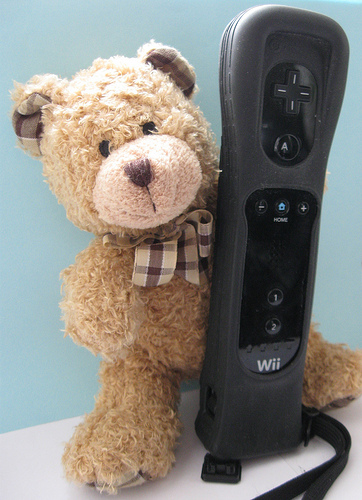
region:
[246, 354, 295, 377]
the wii is gray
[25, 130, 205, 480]
the bear is brown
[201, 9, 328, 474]
the controller is black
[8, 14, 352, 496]
the bear is holding the controller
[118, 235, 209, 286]
the scarf is plaid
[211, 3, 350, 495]
the remote has a strap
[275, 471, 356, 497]
the strap is black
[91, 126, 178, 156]
the bear has eyes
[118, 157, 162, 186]
the bear has a nose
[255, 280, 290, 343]
the remote has buttons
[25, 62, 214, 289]
The bear is brown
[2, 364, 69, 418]
The background is blue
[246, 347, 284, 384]
The controller is for a Wii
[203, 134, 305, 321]
The controller is black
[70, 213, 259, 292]
The bear has a tie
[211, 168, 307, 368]
The controller has buttons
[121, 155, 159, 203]
The bear's nose is dark brown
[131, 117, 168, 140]
The bear's eyes are black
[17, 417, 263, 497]
The bear is on a white object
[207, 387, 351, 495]
The Wii controller has a strap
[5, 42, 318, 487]
the bear is brown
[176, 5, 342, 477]
game controller in front of bear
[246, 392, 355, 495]
controller has a strap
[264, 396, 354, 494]
the strap is black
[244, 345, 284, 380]
controller has white lettering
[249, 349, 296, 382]
the lettering says wii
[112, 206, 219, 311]
bear has plaid pattern on ribbon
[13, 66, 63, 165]
bear's ears are plaid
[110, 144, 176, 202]
bear's nose is brown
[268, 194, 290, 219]
blue button on controller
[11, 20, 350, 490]
Beige teddy bear holding game controller.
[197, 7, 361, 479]
Black WII game controller.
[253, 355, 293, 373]
WII game logo on controller.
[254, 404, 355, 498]
Black strap of game controller.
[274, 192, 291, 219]
Round home button with blue icon.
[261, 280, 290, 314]
Round button on controller with the number 1 on it.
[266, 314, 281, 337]
Round button on controller with the number 2 on it.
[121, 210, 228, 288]
Yellow and brown bow tie on bear.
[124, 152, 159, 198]
Teddy bear's brown nose.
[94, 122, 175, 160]
Teddy bear's dark button eyes.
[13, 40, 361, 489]
a teddy bear standing next to a controller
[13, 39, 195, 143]
the bear has plaid ears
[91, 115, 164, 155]
black eyes are on the bear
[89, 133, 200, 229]
the bear has a pink snout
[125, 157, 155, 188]
the bear's nose is black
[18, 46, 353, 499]
the bear is brown fur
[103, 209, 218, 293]
a plaid ribbon is around the bear's neck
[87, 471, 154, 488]
the bear has plaid feet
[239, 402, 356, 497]
the controller has a wrist band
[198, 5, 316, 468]
the controller is in black case